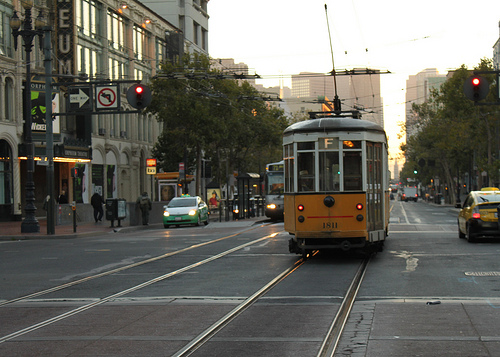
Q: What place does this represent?
A: It represents the road.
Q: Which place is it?
A: It is a road.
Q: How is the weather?
A: It is cloudy.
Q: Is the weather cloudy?
A: Yes, it is cloudy.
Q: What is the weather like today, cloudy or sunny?
A: It is cloudy.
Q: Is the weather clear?
A: No, it is cloudy.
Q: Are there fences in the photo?
A: No, there are no fences.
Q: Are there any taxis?
A: Yes, there is a taxi.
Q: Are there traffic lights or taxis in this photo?
A: Yes, there is a taxi.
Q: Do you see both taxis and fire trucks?
A: No, there is a taxi but no fire trucks.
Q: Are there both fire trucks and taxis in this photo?
A: No, there is a taxi but no fire trucks.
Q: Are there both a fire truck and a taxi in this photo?
A: No, there is a taxi but no fire trucks.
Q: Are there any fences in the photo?
A: No, there are no fences.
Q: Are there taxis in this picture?
A: Yes, there is a taxi.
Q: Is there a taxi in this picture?
A: Yes, there is a taxi.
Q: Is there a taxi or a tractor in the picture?
A: Yes, there is a taxi.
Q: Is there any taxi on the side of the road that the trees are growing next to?
A: Yes, there is a taxi on the side of the road.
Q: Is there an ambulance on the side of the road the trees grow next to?
A: No, there is a taxi on the side of the road.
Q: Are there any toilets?
A: No, there are no toilets.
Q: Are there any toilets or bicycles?
A: No, there are no toilets or bicycles.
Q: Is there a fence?
A: No, there are no fences.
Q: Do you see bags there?
A: No, there are no bags.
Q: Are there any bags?
A: No, there are no bags.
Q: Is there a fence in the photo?
A: No, there are no fences.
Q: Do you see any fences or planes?
A: No, there are no fences or planes.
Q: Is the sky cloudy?
A: Yes, the sky is cloudy.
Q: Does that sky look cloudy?
A: Yes, the sky is cloudy.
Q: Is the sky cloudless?
A: No, the sky is cloudy.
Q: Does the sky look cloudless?
A: No, the sky is cloudy.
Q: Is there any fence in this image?
A: No, there are no fences.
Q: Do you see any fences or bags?
A: No, there are no fences or bags.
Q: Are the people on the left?
A: Yes, the people are on the left of the image.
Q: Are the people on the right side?
A: No, the people are on the left of the image.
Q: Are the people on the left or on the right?
A: The people are on the left of the image.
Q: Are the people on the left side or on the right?
A: The people are on the left of the image.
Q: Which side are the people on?
A: The people are on the left of the image.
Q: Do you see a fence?
A: No, there are no fences.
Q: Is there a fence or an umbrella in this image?
A: No, there are no fences or umbrellas.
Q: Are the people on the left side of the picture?
A: Yes, the people are on the left of the image.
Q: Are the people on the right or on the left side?
A: The people are on the left of the image.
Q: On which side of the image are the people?
A: The people are on the left of the image.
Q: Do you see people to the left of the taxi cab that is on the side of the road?
A: Yes, there are people to the left of the cab.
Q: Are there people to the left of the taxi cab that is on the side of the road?
A: Yes, there are people to the left of the cab.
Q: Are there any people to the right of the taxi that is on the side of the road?
A: No, the people are to the left of the cab.